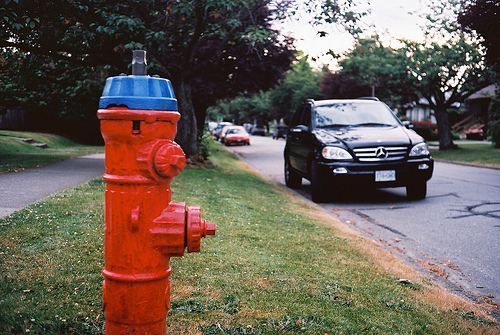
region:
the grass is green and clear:
[230, 168, 322, 328]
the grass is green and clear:
[223, 231, 297, 325]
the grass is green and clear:
[255, 171, 365, 334]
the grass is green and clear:
[174, 108, 329, 332]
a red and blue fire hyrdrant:
[90, 39, 215, 330]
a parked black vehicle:
[272, 91, 432, 208]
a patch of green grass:
[0, 111, 389, 331]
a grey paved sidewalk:
[1, 134, 114, 226]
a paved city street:
[222, 127, 496, 313]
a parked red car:
[215, 123, 255, 153]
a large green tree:
[15, 1, 290, 163]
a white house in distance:
[402, 86, 456, 131]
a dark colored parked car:
[268, 123, 285, 138]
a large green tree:
[346, 39, 463, 151]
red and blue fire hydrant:
[80, 37, 230, 332]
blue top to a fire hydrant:
[90, 61, 191, 133]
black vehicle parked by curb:
[276, 92, 446, 210]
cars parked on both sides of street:
[202, 104, 293, 153]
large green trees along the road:
[8, 6, 325, 163]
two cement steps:
[6, 126, 58, 159]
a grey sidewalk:
[3, 139, 138, 244]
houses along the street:
[375, 79, 498, 153]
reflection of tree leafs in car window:
[302, 95, 362, 131]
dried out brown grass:
[285, 183, 482, 323]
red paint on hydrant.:
[130, 213, 160, 248]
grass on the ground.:
[256, 234, 286, 273]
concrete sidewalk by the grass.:
[17, 176, 49, 196]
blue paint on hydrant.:
[115, 81, 168, 96]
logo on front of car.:
[375, 146, 390, 160]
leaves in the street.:
[417, 249, 457, 273]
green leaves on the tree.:
[206, 49, 240, 75]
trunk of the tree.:
[438, 105, 455, 144]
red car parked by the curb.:
[227, 126, 249, 143]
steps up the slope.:
[24, 135, 45, 150]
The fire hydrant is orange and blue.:
[78, 51, 228, 301]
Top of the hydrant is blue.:
[95, 49, 187, 103]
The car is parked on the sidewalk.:
[269, 85, 435, 204]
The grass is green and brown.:
[223, 204, 353, 322]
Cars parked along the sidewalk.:
[203, 97, 253, 155]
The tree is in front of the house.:
[399, 17, 497, 159]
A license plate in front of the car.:
[353, 158, 413, 198]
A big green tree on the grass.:
[58, 20, 240, 161]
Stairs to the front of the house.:
[26, 123, 68, 166]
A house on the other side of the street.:
[449, 70, 496, 162]